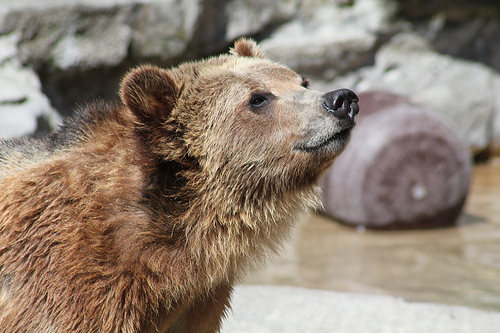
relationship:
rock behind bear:
[258, 0, 415, 82] [1, 36, 360, 332]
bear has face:
[1, 36, 360, 332] [241, 71, 361, 164]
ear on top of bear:
[230, 37, 266, 58] [1, 36, 360, 332]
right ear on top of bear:
[120, 64, 181, 126] [1, 36, 360, 332]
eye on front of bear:
[252, 95, 267, 106] [1, 36, 360, 332]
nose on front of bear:
[321, 88, 360, 120] [1, 36, 360, 332]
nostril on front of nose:
[335, 95, 345, 112] [321, 88, 360, 120]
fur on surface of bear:
[0, 37, 356, 332] [1, 36, 360, 332]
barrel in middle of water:
[311, 87, 474, 230] [235, 153, 499, 311]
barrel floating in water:
[311, 87, 474, 230] [235, 153, 499, 311]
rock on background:
[258, 0, 415, 82] [4, 8, 498, 111]